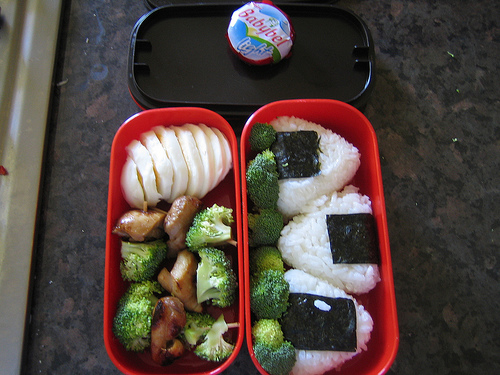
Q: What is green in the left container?
A: Broccoli.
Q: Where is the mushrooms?
A: In the first container.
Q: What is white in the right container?
A: Rice.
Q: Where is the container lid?
A: Above containers.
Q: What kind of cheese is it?
A: Babybel.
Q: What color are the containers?
A: Red.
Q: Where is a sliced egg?
A: In the left container.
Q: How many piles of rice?
A: 3.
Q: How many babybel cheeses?
A: 1.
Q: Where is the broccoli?
A: In both containers.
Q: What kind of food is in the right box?
A: Sushi.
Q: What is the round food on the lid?
A: Cheese.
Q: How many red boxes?
A: Two.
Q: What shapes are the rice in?
A: Triangles.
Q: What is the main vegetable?
A: Broccoli.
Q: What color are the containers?
A: Red.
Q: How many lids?
A: One.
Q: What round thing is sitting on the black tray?
A: Cheese.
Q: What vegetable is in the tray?
A: Broccoli.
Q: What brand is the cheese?
A: Babybel.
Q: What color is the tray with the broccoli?
A: Red.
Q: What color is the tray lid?
A: Black.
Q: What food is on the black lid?
A: Cheese.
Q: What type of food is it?
A: Asian.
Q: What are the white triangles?
A: Rice.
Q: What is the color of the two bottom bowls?
A: Red.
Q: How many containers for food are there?
A: 3.